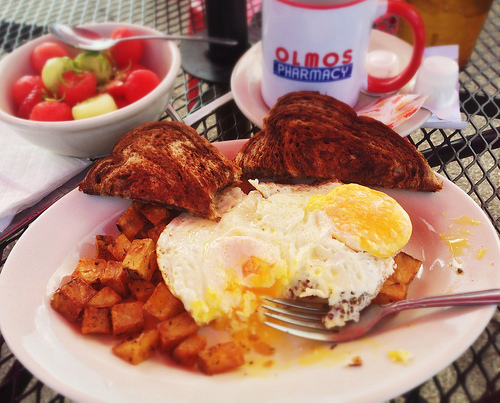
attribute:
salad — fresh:
[13, 25, 149, 125]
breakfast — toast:
[55, 121, 438, 351]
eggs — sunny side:
[178, 182, 392, 322]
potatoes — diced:
[182, 304, 262, 384]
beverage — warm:
[256, 6, 398, 104]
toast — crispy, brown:
[278, 93, 412, 185]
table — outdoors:
[475, 46, 498, 117]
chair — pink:
[188, 3, 268, 111]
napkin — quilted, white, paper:
[6, 135, 56, 209]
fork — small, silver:
[276, 290, 498, 324]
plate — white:
[0, 123, 496, 397]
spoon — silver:
[48, 12, 249, 60]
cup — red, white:
[274, 3, 469, 86]